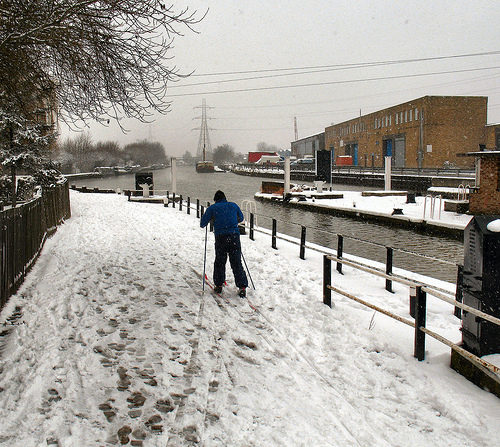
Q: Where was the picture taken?
A: It was taken at the sidewalk.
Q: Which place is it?
A: It is a sidewalk.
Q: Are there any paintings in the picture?
A: No, there are no paintings.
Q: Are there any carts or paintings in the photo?
A: No, there are no paintings or carts.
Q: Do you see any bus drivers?
A: No, there are no bus drivers.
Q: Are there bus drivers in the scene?
A: No, there are no bus drivers.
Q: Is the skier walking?
A: Yes, the skier is walking.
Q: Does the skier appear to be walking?
A: Yes, the skier is walking.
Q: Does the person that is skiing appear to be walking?
A: Yes, the skier is walking.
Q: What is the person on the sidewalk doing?
A: The skier is walking.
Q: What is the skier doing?
A: The skier is walking.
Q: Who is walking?
A: The skier is walking.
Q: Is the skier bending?
A: No, the skier is walking.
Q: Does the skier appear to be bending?
A: No, the skier is walking.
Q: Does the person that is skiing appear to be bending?
A: No, the skier is walking.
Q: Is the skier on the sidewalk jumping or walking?
A: The skier is walking.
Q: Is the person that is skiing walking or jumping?
A: The skier is walking.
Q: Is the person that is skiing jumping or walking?
A: The skier is walking.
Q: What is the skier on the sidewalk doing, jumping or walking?
A: The skier is walking.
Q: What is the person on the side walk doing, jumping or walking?
A: The skier is walking.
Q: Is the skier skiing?
A: Yes, the skier is skiing.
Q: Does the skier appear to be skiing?
A: Yes, the skier is skiing.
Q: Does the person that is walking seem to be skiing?
A: Yes, the skier is skiing.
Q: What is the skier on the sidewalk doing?
A: The skier is skiing.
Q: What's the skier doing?
A: The skier is skiing.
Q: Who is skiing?
A: The skier is skiing.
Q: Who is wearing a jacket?
A: The skier is wearing a jacket.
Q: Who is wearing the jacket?
A: The skier is wearing a jacket.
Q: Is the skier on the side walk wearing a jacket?
A: Yes, the skier is wearing a jacket.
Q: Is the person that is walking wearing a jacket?
A: Yes, the skier is wearing a jacket.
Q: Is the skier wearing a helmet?
A: No, the skier is wearing a jacket.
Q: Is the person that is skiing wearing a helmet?
A: No, the skier is wearing a jacket.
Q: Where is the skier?
A: The skier is on the sidewalk.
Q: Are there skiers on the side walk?
A: Yes, there is a skier on the side walk.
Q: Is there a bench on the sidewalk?
A: No, there is a skier on the sidewalk.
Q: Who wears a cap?
A: The skier wears a cap.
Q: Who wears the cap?
A: The skier wears a cap.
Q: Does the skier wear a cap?
A: Yes, the skier wears a cap.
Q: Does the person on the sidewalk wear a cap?
A: Yes, the skier wears a cap.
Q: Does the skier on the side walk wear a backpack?
A: No, the skier wears a cap.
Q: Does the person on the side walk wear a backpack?
A: No, the skier wears a cap.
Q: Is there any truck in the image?
A: Yes, there is a truck.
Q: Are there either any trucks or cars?
A: Yes, there is a truck.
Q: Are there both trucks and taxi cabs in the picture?
A: No, there is a truck but no taxis.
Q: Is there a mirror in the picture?
A: No, there are no mirrors.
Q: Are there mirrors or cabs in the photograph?
A: No, there are no mirrors or cabs.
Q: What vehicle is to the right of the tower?
A: The vehicle is a truck.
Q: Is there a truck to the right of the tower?
A: Yes, there is a truck to the right of the tower.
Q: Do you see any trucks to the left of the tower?
A: No, the truck is to the right of the tower.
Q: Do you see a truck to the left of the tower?
A: No, the truck is to the right of the tower.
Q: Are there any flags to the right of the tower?
A: No, there is a truck to the right of the tower.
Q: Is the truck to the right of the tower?
A: Yes, the truck is to the right of the tower.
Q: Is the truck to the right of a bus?
A: No, the truck is to the right of the tower.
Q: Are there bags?
A: No, there are no bags.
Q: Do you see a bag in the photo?
A: No, there are no bags.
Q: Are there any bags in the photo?
A: No, there are no bags.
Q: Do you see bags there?
A: No, there are no bags.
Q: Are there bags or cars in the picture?
A: No, there are no bags or cars.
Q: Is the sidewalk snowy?
A: Yes, the sidewalk is snowy.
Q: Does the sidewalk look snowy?
A: Yes, the sidewalk is snowy.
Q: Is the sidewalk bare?
A: No, the sidewalk is snowy.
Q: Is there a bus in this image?
A: No, there are no buses.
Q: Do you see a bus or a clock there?
A: No, there are no buses or clocks.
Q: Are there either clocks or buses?
A: No, there are no buses or clocks.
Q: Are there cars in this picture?
A: No, there are no cars.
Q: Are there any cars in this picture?
A: No, there are no cars.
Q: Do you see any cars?
A: No, there are no cars.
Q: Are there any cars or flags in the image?
A: No, there are no cars or flags.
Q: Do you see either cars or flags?
A: No, there are no cars or flags.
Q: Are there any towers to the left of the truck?
A: Yes, there is a tower to the left of the truck.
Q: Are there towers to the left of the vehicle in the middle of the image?
A: Yes, there is a tower to the left of the truck.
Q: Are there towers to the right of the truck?
A: No, the tower is to the left of the truck.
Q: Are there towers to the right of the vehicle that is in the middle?
A: No, the tower is to the left of the truck.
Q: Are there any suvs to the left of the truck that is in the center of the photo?
A: No, there is a tower to the left of the truck.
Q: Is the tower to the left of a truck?
A: Yes, the tower is to the left of a truck.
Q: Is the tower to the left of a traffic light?
A: No, the tower is to the left of a truck.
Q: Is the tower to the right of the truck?
A: No, the tower is to the left of the truck.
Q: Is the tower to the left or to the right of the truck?
A: The tower is to the left of the truck.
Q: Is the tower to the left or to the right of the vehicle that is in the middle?
A: The tower is to the left of the truck.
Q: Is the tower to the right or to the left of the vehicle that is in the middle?
A: The tower is to the left of the truck.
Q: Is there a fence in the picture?
A: Yes, there is a fence.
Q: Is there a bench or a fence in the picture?
A: Yes, there is a fence.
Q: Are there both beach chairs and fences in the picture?
A: No, there is a fence but no beach chairs.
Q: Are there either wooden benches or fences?
A: Yes, there is a wood fence.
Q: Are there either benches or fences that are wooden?
A: Yes, the fence is wooden.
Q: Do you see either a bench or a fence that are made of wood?
A: Yes, the fence is made of wood.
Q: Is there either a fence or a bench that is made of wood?
A: Yes, the fence is made of wood.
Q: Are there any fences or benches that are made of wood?
A: Yes, the fence is made of wood.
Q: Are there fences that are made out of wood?
A: Yes, there is a fence that is made of wood.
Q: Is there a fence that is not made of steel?
A: Yes, there is a fence that is made of wood.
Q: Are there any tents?
A: No, there are no tents.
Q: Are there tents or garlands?
A: No, there are no tents or garlands.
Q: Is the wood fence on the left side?
A: Yes, the fence is on the left of the image.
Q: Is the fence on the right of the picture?
A: No, the fence is on the left of the image.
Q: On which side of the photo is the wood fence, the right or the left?
A: The fence is on the left of the image.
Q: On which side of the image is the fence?
A: The fence is on the left of the image.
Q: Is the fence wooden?
A: Yes, the fence is wooden.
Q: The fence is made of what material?
A: The fence is made of wood.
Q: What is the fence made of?
A: The fence is made of wood.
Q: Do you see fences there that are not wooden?
A: No, there is a fence but it is wooden.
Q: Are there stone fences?
A: No, there is a fence but it is made of wood.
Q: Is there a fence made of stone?
A: No, there is a fence but it is made of wood.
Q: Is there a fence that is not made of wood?
A: No, there is a fence but it is made of wood.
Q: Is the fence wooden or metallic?
A: The fence is wooden.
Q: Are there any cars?
A: No, there are no cars.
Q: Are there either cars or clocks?
A: No, there are no cars or clocks.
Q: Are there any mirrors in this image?
A: No, there are no mirrors.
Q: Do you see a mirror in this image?
A: No, there are no mirrors.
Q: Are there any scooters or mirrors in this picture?
A: No, there are no mirrors or scooters.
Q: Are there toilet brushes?
A: No, there are no toilet brushes.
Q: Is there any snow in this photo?
A: Yes, there is snow.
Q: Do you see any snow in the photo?
A: Yes, there is snow.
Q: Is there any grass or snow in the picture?
A: Yes, there is snow.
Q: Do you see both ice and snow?
A: No, there is snow but no ice.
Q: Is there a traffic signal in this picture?
A: No, there are no traffic lights.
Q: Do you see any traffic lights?
A: No, there are no traffic lights.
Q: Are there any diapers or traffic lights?
A: No, there are no traffic lights or diapers.